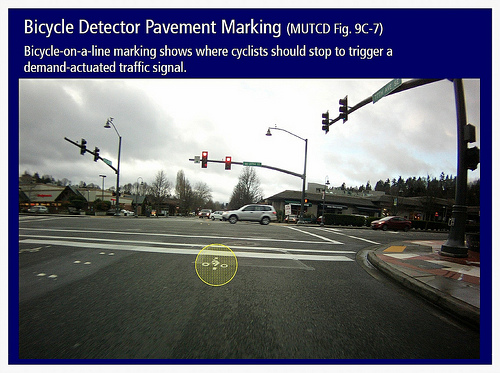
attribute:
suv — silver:
[208, 198, 288, 227]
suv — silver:
[210, 197, 282, 229]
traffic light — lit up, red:
[197, 149, 211, 168]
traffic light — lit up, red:
[222, 151, 233, 172]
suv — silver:
[220, 198, 283, 226]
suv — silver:
[225, 203, 282, 225]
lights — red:
[200, 150, 236, 171]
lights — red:
[198, 151, 232, 171]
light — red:
[199, 150, 209, 169]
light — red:
[223, 156, 233, 170]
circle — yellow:
[193, 240, 240, 289]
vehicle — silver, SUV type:
[220, 201, 279, 225]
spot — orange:
[382, 243, 408, 254]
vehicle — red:
[368, 213, 419, 232]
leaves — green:
[377, 179, 395, 195]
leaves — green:
[397, 177, 426, 188]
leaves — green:
[430, 175, 450, 191]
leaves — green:
[27, 170, 49, 183]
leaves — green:
[425, 176, 451, 195]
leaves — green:
[406, 176, 428, 193]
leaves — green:
[371, 176, 390, 192]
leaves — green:
[184, 184, 193, 211]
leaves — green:
[405, 172, 425, 193]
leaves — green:
[383, 174, 409, 194]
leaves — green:
[229, 184, 252, 204]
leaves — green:
[178, 179, 192, 211]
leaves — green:
[433, 174, 455, 194]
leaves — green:
[391, 176, 419, 196]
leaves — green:
[338, 180, 357, 192]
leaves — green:
[437, 169, 457, 195]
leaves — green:
[360, 177, 388, 191]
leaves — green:
[387, 176, 409, 192]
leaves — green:
[182, 173, 202, 203]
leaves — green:
[398, 176, 419, 186]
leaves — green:
[413, 168, 433, 190]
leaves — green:
[401, 169, 417, 183]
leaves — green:
[438, 174, 450, 203]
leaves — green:
[230, 156, 264, 203]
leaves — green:
[183, 180, 203, 210]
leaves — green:
[156, 168, 171, 183]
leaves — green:
[154, 167, 166, 189]